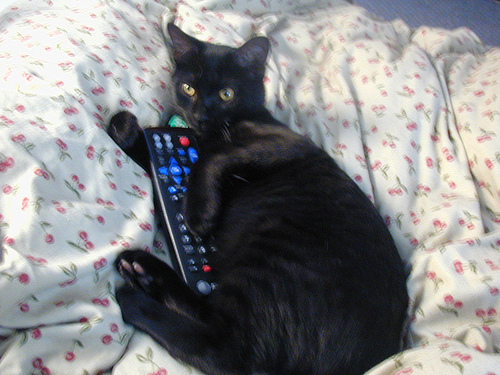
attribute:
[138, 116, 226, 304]
remote control — large, blurry, black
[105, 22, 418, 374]
cat — very small, blurry, black, laying down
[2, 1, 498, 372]
blanket — blurry, cherry patterned, white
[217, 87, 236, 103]
eye — yellow gold, yellow, green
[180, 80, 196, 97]
eye — yellow gold, yellow, green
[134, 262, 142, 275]
paw pad — pinky-purply, pink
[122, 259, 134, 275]
paw pad — pinky-purply, pink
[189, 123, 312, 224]
foreleg — lighter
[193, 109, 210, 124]
nose — black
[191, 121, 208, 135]
mouth — black, almost hidden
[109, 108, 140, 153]
right forepaw — curled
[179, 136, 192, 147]
button — red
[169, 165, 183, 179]
button — blue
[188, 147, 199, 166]
button — blue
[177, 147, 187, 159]
button — blue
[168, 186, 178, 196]
button — blue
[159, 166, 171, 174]
button — blue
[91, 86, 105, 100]
cherry — red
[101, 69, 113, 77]
cherry — red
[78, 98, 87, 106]
cherry — red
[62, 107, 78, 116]
cherry — red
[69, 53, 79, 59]
cherry — red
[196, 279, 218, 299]
button — grey